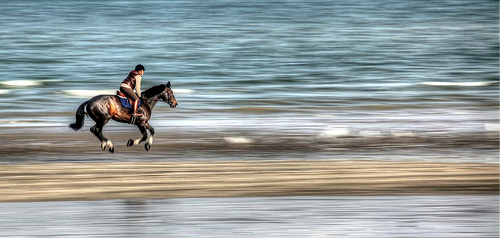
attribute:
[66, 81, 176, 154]
horse — brown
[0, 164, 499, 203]
sandbar — brown, tan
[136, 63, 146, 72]
helmet — black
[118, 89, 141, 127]
saddle — brown, blue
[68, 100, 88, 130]
tail — black, curved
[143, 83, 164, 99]
mane — black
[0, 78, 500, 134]
waves — white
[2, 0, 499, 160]
water — blue, rippled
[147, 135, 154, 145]
part of leg — white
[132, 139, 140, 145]
part of leg — white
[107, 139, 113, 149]
part of leg — white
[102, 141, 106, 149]
part of leg — white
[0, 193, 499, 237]
water — grey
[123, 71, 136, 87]
vest — brown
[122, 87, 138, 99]
pants — brown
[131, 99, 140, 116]
boots — brown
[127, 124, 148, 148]
leg — black, white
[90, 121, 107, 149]
leg — black, white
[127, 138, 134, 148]
feet — black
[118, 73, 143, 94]
shirt — tan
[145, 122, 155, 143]
leg — black, white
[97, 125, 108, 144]
leg — black, white